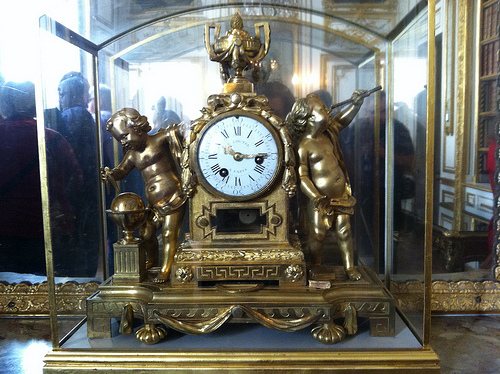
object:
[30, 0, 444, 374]
case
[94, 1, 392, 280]
mirror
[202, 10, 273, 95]
trophy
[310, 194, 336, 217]
statue hand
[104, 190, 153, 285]
statue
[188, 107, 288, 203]
clock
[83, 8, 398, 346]
statue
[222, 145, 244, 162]
hand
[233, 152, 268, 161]
hand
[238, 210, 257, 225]
bell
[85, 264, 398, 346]
bottom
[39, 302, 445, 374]
stand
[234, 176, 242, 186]
six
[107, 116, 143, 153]
face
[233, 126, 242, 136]
numbers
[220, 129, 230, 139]
numerals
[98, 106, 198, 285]
children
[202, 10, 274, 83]
carving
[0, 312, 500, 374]
table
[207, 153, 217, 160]
numerals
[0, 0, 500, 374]
museum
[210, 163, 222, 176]
numerals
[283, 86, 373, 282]
children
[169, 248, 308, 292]
design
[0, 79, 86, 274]
people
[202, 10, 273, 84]
statue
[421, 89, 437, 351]
frame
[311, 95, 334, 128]
face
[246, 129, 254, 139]
one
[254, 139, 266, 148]
two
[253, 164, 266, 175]
four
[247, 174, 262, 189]
five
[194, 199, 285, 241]
design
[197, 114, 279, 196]
glass